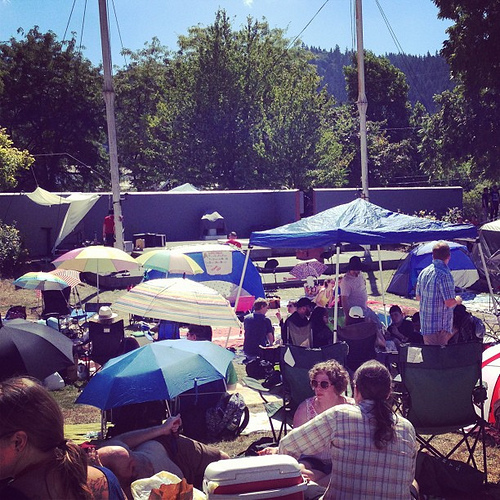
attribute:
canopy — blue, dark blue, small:
[241, 194, 484, 253]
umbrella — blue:
[73, 333, 241, 411]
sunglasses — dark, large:
[304, 371, 342, 392]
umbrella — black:
[2, 317, 88, 383]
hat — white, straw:
[93, 304, 122, 326]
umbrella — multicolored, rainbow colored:
[54, 240, 143, 289]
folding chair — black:
[79, 317, 132, 365]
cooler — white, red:
[198, 442, 315, 500]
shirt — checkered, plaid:
[282, 401, 423, 499]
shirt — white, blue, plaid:
[406, 263, 464, 332]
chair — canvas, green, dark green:
[397, 360, 499, 473]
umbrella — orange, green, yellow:
[135, 245, 206, 283]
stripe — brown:
[97, 310, 115, 322]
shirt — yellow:
[313, 288, 340, 313]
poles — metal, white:
[239, 245, 499, 340]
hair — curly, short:
[301, 358, 353, 393]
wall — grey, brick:
[1, 187, 475, 236]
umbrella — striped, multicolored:
[114, 277, 240, 336]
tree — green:
[140, 1, 352, 196]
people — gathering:
[2, 194, 498, 498]